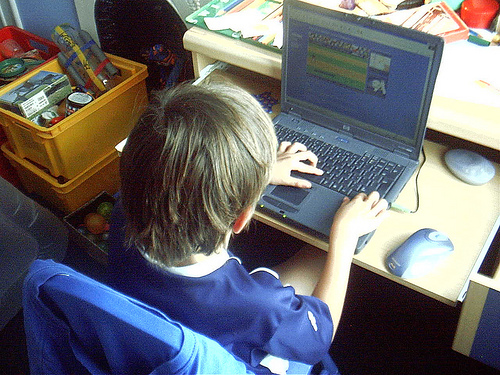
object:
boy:
[93, 81, 387, 375]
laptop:
[255, 0, 444, 256]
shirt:
[23, 257, 254, 375]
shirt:
[93, 236, 337, 374]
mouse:
[384, 228, 455, 279]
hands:
[333, 191, 388, 237]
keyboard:
[276, 123, 406, 200]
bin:
[0, 49, 149, 179]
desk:
[182, 0, 500, 312]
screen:
[285, 4, 435, 148]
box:
[0, 70, 75, 127]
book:
[184, 0, 299, 54]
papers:
[202, 10, 262, 32]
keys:
[359, 177, 372, 186]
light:
[413, 245, 449, 279]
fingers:
[292, 161, 324, 175]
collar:
[132, 236, 232, 279]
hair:
[116, 81, 279, 270]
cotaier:
[459, 0, 499, 30]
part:
[280, 152, 300, 170]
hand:
[270, 140, 324, 189]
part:
[423, 234, 432, 249]